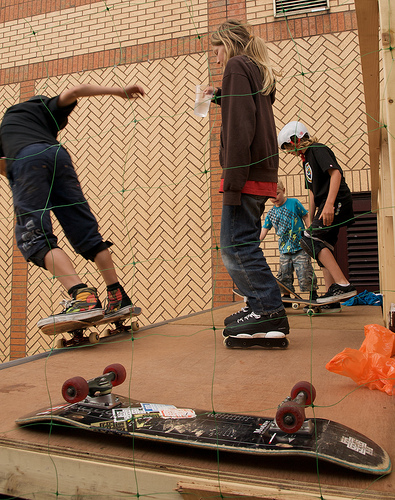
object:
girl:
[186, 9, 306, 366]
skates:
[216, 294, 295, 358]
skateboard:
[10, 355, 395, 484]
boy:
[0, 71, 152, 340]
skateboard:
[32, 287, 145, 361]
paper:
[322, 314, 395, 404]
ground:
[0, 277, 395, 500]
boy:
[274, 109, 362, 313]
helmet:
[276, 119, 312, 152]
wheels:
[272, 394, 310, 440]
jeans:
[212, 183, 292, 319]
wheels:
[85, 328, 103, 347]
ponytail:
[244, 29, 278, 99]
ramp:
[328, 199, 383, 306]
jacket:
[214, 51, 288, 208]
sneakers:
[314, 280, 358, 309]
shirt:
[300, 137, 358, 231]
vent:
[266, 0, 335, 23]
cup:
[188, 76, 219, 125]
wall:
[0, 0, 394, 362]